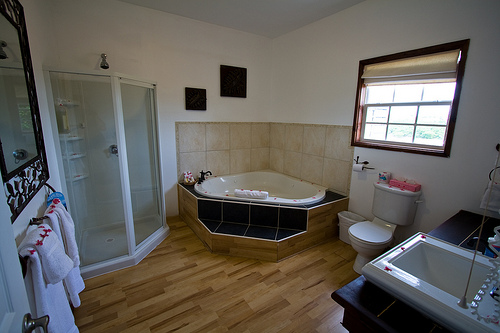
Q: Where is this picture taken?
A: A bathroom.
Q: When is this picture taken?
A: Daytime.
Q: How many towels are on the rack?
A: 4.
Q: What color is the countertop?
A: Black.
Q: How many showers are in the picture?
A: 1.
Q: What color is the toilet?
A: White.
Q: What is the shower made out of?
A: Glass.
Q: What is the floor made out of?
A: Wood.